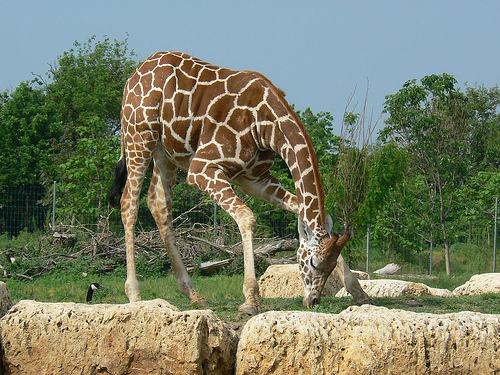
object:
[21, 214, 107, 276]
branches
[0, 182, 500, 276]
fence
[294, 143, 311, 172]
brown spot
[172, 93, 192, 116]
brown spot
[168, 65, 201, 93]
spot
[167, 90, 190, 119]
patches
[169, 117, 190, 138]
patches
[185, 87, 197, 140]
line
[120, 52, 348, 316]
giraffe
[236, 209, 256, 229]
knee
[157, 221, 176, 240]
knee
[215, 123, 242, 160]
spot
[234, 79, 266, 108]
spot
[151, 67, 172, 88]
spot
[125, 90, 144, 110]
spot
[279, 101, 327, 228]
neck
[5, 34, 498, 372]
wildlife park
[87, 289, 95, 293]
neck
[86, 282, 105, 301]
bird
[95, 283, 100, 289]
face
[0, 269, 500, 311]
grass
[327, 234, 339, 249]
horn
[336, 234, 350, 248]
horn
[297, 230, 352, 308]
head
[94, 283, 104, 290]
head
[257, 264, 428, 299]
rock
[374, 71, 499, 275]
tree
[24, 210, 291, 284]
brush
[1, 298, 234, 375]
stone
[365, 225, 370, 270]
pole